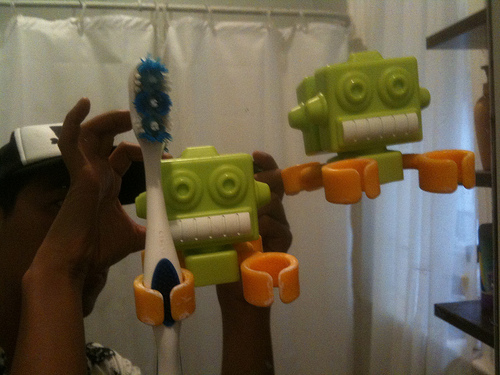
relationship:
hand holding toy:
[11, 97, 172, 375] [111, 136, 311, 330]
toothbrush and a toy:
[113, 47, 177, 251] [116, 128, 262, 310]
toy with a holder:
[129, 137, 269, 305] [141, 240, 303, 308]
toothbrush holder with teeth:
[279, 49, 474, 204] [336, 114, 415, 146]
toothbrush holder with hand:
[279, 49, 474, 204] [313, 145, 386, 217]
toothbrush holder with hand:
[279, 49, 474, 204] [414, 141, 487, 209]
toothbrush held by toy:
[127, 59, 182, 375] [111, 139, 286, 310]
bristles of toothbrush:
[132, 55, 176, 145] [127, 59, 182, 375]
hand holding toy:
[11, 97, 172, 375] [122, 118, 313, 346]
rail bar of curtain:
[4, 0, 367, 38] [10, 20, 350, 270]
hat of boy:
[6, 110, 109, 182] [18, 103, 123, 321]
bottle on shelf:
[463, 60, 498, 162] [425, 0, 500, 372]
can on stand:
[462, 221, 497, 282] [423, 290, 488, 332]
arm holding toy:
[191, 141, 309, 371] [130, 141, 314, 331]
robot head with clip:
[126, 152, 266, 269] [132, 268, 195, 325]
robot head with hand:
[126, 152, 266, 269] [243, 245, 306, 296]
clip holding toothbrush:
[132, 268, 195, 325] [110, 55, 205, 285]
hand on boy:
[18, 95, 145, 285] [0, 98, 293, 375]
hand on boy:
[213, 150, 294, 309] [0, 98, 293, 375]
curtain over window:
[344, 0, 496, 373] [347, 0, 494, 370]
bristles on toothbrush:
[133, 55, 175, 145] [122, 52, 186, 372]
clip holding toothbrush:
[130, 260, 200, 327] [122, 52, 186, 372]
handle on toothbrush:
[143, 208, 185, 375] [122, 52, 186, 372]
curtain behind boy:
[2, 14, 350, 375] [0, 98, 293, 375]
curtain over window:
[344, 0, 496, 373] [380, 35, 480, 351]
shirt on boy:
[83, 339, 139, 375] [0, 98, 293, 375]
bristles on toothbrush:
[132, 55, 176, 145] [126, 50, 183, 373]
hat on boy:
[0, 123, 147, 206] [0, 98, 293, 375]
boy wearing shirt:
[0, 98, 293, 375] [81, 339, 148, 373]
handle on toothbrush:
[141, 226, 187, 373] [127, 55, 189, 373]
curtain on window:
[344, 0, 496, 373] [376, 47, 491, 360]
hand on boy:
[11, 97, 172, 375] [0, 98, 293, 375]